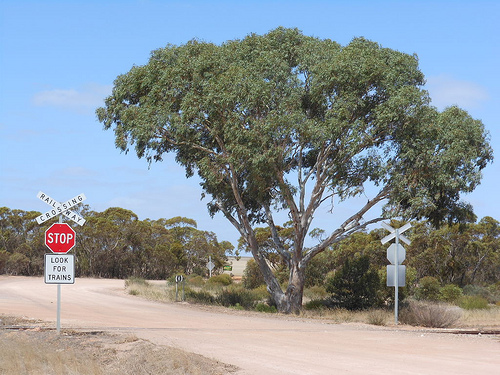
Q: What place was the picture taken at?
A: It was taken at the road.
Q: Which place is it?
A: It is a road.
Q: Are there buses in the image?
A: No, there are no buses.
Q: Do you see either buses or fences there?
A: No, there are no buses or fences.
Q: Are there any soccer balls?
A: No, there are no soccer balls.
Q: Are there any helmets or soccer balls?
A: No, there are no soccer balls or helmets.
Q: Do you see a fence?
A: No, there are no fences.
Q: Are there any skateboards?
A: No, there are no skateboards.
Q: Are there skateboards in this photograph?
A: No, there are no skateboards.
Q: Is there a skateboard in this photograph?
A: No, there are no skateboards.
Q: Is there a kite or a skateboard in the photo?
A: No, there are no skateboards or kites.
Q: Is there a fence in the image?
A: No, there are no fences.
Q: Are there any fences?
A: No, there are no fences.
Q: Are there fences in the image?
A: No, there are no fences.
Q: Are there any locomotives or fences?
A: No, there are no fences or locomotives.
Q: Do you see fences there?
A: No, there are no fences.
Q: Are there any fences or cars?
A: No, there are no fences or cars.